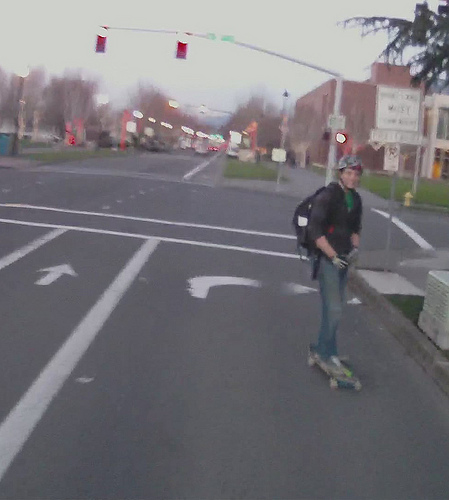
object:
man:
[305, 152, 363, 370]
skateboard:
[306, 342, 360, 389]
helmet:
[331, 153, 361, 170]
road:
[0, 248, 448, 499]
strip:
[0, 237, 161, 474]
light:
[175, 41, 189, 59]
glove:
[331, 251, 346, 267]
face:
[337, 167, 362, 190]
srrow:
[30, 235, 102, 294]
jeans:
[314, 260, 346, 358]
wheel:
[329, 378, 338, 389]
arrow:
[31, 263, 76, 287]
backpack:
[293, 186, 323, 249]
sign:
[326, 114, 342, 132]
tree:
[332, 0, 448, 98]